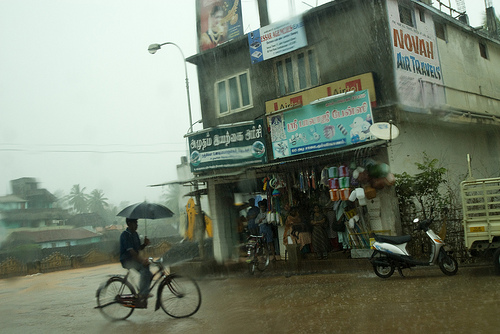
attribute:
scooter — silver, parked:
[350, 212, 491, 282]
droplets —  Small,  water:
[389, 279, 485, 326]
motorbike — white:
[369, 215, 459, 279]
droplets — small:
[248, 297, 265, 314]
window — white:
[213, 82, 227, 114]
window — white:
[225, 80, 237, 108]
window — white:
[235, 73, 249, 108]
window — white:
[271, 64, 284, 94]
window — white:
[283, 62, 294, 92]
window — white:
[296, 54, 306, 92]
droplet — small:
[373, 295, 378, 300]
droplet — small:
[419, 285, 422, 287]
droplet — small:
[319, 290, 322, 292]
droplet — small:
[476, 304, 480, 306]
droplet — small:
[325, 307, 327, 310]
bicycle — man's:
[86, 258, 204, 333]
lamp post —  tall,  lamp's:
[154, 34, 223, 246]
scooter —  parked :
[333, 196, 499, 283]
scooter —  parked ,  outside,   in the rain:
[368, 217, 458, 279]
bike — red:
[245, 227, 267, 276]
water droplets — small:
[250, 272, 499, 332]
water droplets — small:
[220, 272, 498, 332]